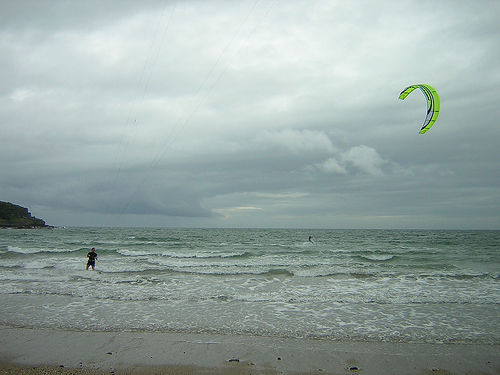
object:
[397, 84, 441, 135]
kite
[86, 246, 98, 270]
man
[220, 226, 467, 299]
water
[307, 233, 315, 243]
person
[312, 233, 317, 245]
surfboard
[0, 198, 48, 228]
part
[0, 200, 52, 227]
land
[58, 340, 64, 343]
sand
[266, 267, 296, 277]
waves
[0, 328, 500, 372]
shore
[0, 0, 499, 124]
clouds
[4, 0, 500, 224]
sky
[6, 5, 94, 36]
no birds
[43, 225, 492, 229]
horizon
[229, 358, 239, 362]
rock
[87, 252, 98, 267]
black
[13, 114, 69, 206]
left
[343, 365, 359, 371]
seaweed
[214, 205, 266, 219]
su